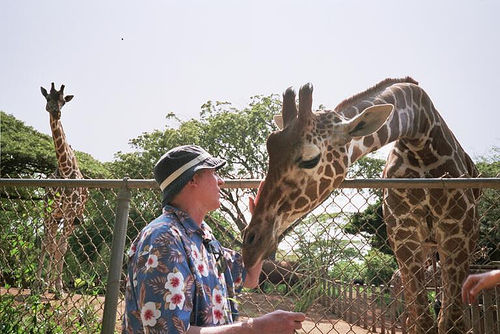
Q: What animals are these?
A: Giraffes.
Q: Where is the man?
A: By the giraffes.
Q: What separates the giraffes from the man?
A: A fence.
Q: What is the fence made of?
A: Metal.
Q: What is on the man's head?
A: A hat.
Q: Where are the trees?
A: Behind the giraffes.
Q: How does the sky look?
A: Clear and blue.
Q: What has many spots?
A: Giraffe.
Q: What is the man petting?
A: The giraffe.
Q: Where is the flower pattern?
A: Man's shirt.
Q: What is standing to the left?
A: Giraffe.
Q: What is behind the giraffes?
A: Trees.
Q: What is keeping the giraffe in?
A: Fence.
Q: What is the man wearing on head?
A: Hat.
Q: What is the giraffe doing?
A: Looking at the man.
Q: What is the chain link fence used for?
A: Safety.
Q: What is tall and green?
A: Trees.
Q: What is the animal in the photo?
A: Giraffe.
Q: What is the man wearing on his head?
A: Hat.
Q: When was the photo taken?
A: Morning.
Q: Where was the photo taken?
A: Zoo.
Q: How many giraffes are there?
A: Two.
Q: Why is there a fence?
A: Safety.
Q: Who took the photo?
A: Tourist.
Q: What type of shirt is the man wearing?
A: Hawaiian.